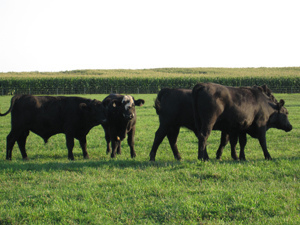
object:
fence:
[0, 82, 300, 96]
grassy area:
[0, 95, 299, 164]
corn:
[0, 66, 300, 96]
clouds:
[208, 29, 261, 62]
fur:
[233, 96, 257, 117]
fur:
[166, 96, 194, 117]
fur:
[110, 106, 124, 129]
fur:
[33, 99, 83, 127]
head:
[274, 99, 292, 133]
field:
[165, 174, 239, 204]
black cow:
[100, 93, 145, 158]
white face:
[120, 95, 135, 114]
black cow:
[149, 85, 278, 161]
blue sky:
[104, 21, 175, 46]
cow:
[191, 81, 293, 162]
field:
[78, 142, 236, 190]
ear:
[279, 99, 285, 106]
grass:
[253, 169, 274, 222]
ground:
[154, 159, 249, 191]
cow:
[0, 94, 112, 161]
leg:
[258, 132, 272, 161]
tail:
[0, 96, 16, 117]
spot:
[121, 95, 134, 110]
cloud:
[38, 14, 131, 40]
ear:
[135, 98, 146, 106]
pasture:
[0, 62, 300, 187]